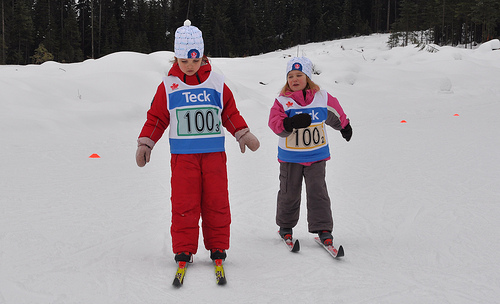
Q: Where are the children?
A: On the snow.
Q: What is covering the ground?
A: White snow.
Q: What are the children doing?
A: Skiing.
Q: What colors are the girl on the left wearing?
A: Red and white.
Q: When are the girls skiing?
A: Afternoon.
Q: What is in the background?
A: Trees.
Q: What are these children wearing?
A: Snow suits.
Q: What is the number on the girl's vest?
A: 100.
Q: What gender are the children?
A: Girls.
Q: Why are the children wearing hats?
A: It's cold.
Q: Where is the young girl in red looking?
A: Ground.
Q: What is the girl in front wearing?
A: Red snowsuit.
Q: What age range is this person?
A: Child.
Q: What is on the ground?
A: Snow.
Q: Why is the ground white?
A: Snow.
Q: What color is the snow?
A: White.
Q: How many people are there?
A: Two.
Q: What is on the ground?
A: Snow.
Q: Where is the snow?
A: On the ground.